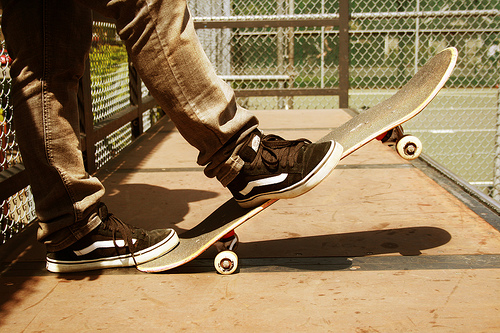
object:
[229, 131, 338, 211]
sneaker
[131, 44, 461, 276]
skateboard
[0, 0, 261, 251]
jeans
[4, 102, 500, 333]
ramp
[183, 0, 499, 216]
fence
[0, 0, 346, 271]
man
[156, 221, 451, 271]
shadow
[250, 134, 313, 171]
laces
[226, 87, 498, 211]
court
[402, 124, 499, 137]
line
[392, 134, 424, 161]
wheel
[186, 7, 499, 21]
post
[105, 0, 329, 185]
leg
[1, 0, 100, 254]
leg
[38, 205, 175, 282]
shoes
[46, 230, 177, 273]
soles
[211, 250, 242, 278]
wheels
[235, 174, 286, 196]
stripe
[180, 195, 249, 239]
shadow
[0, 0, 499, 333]
background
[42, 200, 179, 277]
feet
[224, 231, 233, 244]
details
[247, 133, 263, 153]
tag